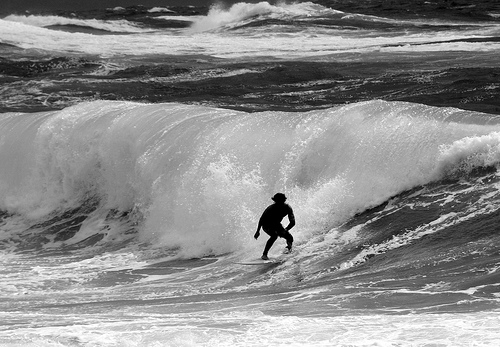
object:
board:
[233, 248, 293, 265]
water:
[352, 217, 475, 309]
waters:
[2, 99, 492, 261]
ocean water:
[3, 3, 495, 345]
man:
[254, 192, 296, 260]